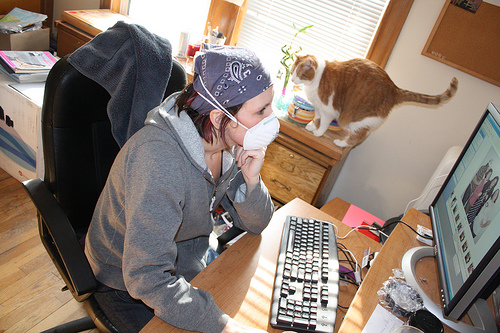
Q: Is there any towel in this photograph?
A: Yes, there is a towel.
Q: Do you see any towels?
A: Yes, there is a towel.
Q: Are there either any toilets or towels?
A: Yes, there is a towel.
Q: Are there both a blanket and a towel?
A: No, there is a towel but no blankets.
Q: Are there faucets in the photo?
A: No, there are no faucets.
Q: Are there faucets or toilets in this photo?
A: No, there are no faucets or toilets.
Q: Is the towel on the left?
A: Yes, the towel is on the left of the image.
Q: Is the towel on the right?
A: No, the towel is on the left of the image.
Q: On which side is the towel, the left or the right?
A: The towel is on the left of the image.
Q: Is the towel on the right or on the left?
A: The towel is on the left of the image.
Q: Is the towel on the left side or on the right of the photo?
A: The towel is on the left of the image.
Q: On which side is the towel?
A: The towel is on the left of the image.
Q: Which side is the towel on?
A: The towel is on the left of the image.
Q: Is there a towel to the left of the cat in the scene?
A: Yes, there is a towel to the left of the cat.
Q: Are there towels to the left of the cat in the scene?
A: Yes, there is a towel to the left of the cat.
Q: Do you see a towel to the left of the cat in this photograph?
A: Yes, there is a towel to the left of the cat.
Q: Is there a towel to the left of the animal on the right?
A: Yes, there is a towel to the left of the cat.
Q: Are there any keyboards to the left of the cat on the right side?
A: No, there is a towel to the left of the cat.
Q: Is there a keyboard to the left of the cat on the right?
A: No, there is a towel to the left of the cat.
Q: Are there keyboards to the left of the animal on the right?
A: No, there is a towel to the left of the cat.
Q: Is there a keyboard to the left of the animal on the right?
A: No, there is a towel to the left of the cat.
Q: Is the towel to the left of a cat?
A: Yes, the towel is to the left of a cat.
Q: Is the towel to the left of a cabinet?
A: No, the towel is to the left of a cat.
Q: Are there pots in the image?
A: No, there are no pots.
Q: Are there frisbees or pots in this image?
A: No, there are no pots or frisbees.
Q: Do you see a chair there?
A: Yes, there is a chair.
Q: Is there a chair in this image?
A: Yes, there is a chair.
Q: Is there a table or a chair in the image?
A: Yes, there is a chair.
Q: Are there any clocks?
A: No, there are no clocks.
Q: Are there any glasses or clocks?
A: No, there are no clocks or glasses.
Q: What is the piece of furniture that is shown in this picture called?
A: The piece of furniture is a chair.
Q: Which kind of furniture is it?
A: The piece of furniture is a chair.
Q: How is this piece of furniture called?
A: This is a chair.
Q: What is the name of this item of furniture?
A: This is a chair.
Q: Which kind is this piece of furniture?
A: This is a chair.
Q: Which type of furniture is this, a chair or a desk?
A: This is a chair.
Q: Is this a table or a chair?
A: This is a chair.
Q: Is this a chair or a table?
A: This is a chair.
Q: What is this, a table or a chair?
A: This is a chair.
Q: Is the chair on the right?
A: No, the chair is on the left of the image.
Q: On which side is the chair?
A: The chair is on the left of the image.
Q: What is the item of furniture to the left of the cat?
A: The piece of furniture is a chair.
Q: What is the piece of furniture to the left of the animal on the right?
A: The piece of furniture is a chair.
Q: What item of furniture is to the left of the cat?
A: The piece of furniture is a chair.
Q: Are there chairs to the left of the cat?
A: Yes, there is a chair to the left of the cat.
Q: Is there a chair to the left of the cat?
A: Yes, there is a chair to the left of the cat.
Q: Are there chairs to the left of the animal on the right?
A: Yes, there is a chair to the left of the cat.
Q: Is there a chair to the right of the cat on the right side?
A: No, the chair is to the left of the cat.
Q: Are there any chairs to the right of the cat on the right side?
A: No, the chair is to the left of the cat.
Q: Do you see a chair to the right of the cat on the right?
A: No, the chair is to the left of the cat.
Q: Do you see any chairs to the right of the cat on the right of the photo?
A: No, the chair is to the left of the cat.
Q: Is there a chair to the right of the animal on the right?
A: No, the chair is to the left of the cat.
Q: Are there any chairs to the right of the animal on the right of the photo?
A: No, the chair is to the left of the cat.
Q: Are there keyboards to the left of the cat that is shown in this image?
A: No, there is a chair to the left of the cat.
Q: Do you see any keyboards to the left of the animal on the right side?
A: No, there is a chair to the left of the cat.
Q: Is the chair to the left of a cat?
A: Yes, the chair is to the left of a cat.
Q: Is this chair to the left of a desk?
A: No, the chair is to the left of a cat.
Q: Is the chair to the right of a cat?
A: No, the chair is to the left of a cat.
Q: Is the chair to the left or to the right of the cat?
A: The chair is to the left of the cat.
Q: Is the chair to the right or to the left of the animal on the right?
A: The chair is to the left of the cat.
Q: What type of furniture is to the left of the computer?
A: The piece of furniture is a chair.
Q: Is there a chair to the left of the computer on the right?
A: Yes, there is a chair to the left of the computer.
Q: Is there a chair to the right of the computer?
A: No, the chair is to the left of the computer.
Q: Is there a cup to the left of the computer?
A: No, there is a chair to the left of the computer.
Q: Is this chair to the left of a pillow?
A: No, the chair is to the left of a computer.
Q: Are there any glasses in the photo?
A: No, there are no glasses.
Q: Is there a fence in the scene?
A: No, there are no fences.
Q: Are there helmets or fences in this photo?
A: No, there are no fences or helmets.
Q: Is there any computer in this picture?
A: Yes, there is a computer.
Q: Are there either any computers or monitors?
A: Yes, there is a computer.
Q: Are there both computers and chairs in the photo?
A: Yes, there are both a computer and a chair.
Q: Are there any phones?
A: No, there are no phones.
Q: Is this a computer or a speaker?
A: This is a computer.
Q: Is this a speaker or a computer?
A: This is a computer.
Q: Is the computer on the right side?
A: Yes, the computer is on the right of the image.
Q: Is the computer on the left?
A: No, the computer is on the right of the image.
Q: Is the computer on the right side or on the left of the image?
A: The computer is on the right of the image.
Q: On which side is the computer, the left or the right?
A: The computer is on the right of the image.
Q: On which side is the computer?
A: The computer is on the right of the image.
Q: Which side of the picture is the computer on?
A: The computer is on the right of the image.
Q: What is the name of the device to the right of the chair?
A: The device is a computer.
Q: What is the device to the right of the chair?
A: The device is a computer.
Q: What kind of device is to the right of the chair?
A: The device is a computer.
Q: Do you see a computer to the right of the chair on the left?
A: Yes, there is a computer to the right of the chair.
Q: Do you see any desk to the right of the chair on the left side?
A: No, there is a computer to the right of the chair.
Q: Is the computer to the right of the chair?
A: Yes, the computer is to the right of the chair.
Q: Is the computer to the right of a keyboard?
A: No, the computer is to the right of the chair.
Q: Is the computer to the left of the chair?
A: No, the computer is to the right of the chair.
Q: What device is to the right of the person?
A: The device is a computer.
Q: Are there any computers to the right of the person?
A: Yes, there is a computer to the right of the person.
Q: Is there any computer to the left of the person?
A: No, the computer is to the right of the person.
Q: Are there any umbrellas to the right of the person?
A: No, there is a computer to the right of the person.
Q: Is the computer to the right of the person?
A: Yes, the computer is to the right of the person.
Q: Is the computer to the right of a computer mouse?
A: No, the computer is to the right of the person.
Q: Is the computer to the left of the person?
A: No, the computer is to the right of the person.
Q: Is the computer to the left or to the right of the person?
A: The computer is to the right of the person.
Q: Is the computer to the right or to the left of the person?
A: The computer is to the right of the person.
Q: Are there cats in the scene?
A: Yes, there is a cat.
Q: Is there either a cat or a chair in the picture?
A: Yes, there is a cat.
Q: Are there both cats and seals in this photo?
A: No, there is a cat but no seals.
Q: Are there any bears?
A: No, there are no bears.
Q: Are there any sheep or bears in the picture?
A: No, there are no bears or sheep.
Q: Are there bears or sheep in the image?
A: No, there are no bears or sheep.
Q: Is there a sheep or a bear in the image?
A: No, there are no bears or sheep.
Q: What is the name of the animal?
A: The animal is a cat.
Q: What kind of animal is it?
A: The animal is a cat.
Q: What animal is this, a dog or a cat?
A: This is a cat.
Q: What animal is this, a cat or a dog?
A: This is a cat.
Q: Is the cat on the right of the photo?
A: Yes, the cat is on the right of the image.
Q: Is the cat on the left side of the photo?
A: No, the cat is on the right of the image.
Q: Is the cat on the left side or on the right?
A: The cat is on the right of the image.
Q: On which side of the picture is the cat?
A: The cat is on the right of the image.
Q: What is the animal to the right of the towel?
A: The animal is a cat.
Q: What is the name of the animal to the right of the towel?
A: The animal is a cat.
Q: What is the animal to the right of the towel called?
A: The animal is a cat.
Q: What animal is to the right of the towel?
A: The animal is a cat.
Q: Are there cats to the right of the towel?
A: Yes, there is a cat to the right of the towel.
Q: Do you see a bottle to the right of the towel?
A: No, there is a cat to the right of the towel.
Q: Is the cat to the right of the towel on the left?
A: Yes, the cat is to the right of the towel.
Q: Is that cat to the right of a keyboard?
A: No, the cat is to the right of the towel.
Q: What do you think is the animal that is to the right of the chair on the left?
A: The animal is a cat.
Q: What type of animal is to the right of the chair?
A: The animal is a cat.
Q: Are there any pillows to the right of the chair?
A: No, there is a cat to the right of the chair.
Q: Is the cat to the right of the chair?
A: Yes, the cat is to the right of the chair.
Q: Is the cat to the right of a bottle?
A: No, the cat is to the right of the chair.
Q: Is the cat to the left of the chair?
A: No, the cat is to the right of the chair.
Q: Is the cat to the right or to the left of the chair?
A: The cat is to the right of the chair.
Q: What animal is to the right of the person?
A: The animal is a cat.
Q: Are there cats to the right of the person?
A: Yes, there is a cat to the right of the person.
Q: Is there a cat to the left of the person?
A: No, the cat is to the right of the person.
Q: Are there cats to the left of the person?
A: No, the cat is to the right of the person.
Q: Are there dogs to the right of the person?
A: No, there is a cat to the right of the person.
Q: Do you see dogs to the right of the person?
A: No, there is a cat to the right of the person.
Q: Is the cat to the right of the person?
A: Yes, the cat is to the right of the person.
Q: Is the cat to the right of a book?
A: No, the cat is to the right of the person.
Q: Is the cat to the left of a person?
A: No, the cat is to the right of a person.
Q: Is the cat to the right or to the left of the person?
A: The cat is to the right of the person.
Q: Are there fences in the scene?
A: No, there are no fences.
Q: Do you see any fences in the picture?
A: No, there are no fences.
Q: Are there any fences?
A: No, there are no fences.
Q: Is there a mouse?
A: No, there are no computer mice.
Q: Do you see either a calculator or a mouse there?
A: No, there are no computer mice or calculators.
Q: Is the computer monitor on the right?
A: Yes, the computer monitor is on the right of the image.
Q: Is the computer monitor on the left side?
A: No, the computer monitor is on the right of the image.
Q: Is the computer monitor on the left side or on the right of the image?
A: The computer monitor is on the right of the image.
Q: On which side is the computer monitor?
A: The computer monitor is on the right of the image.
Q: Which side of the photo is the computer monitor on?
A: The computer monitor is on the right of the image.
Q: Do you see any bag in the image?
A: No, there are no bags.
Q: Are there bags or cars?
A: No, there are no bags or cars.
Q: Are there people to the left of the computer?
A: Yes, there is a person to the left of the computer.